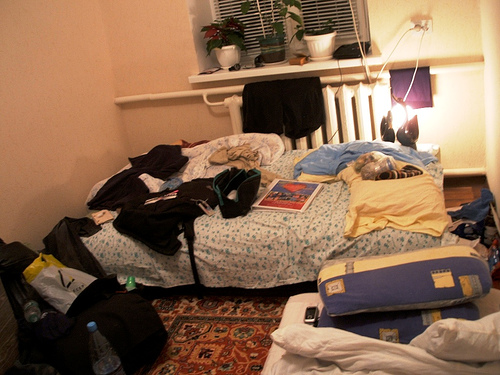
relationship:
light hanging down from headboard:
[386, 100, 414, 134] [216, 60, 448, 182]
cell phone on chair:
[303, 302, 319, 324] [261, 283, 496, 374]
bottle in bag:
[106, 276, 157, 301] [81, 251, 196, 349]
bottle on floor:
[85, 321, 123, 371] [172, 302, 261, 369]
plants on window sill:
[196, 0, 336, 58] [190, 45, 385, 82]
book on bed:
[250, 170, 330, 215] [67, 139, 457, 284]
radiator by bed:
[201, 78, 391, 153] [70, 148, 445, 294]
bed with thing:
[68, 139, 448, 300] [112, 172, 219, 256]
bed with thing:
[68, 139, 448, 300] [213, 137, 277, 194]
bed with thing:
[68, 139, 448, 300] [211, 163, 260, 217]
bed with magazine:
[68, 139, 448, 300] [250, 178, 325, 213]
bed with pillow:
[68, 139, 448, 300] [334, 160, 450, 238]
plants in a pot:
[196, 0, 336, 58] [217, 44, 245, 74]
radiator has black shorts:
[210, 76, 403, 154] [240, 76, 326, 140]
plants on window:
[196, 1, 343, 68] [192, 6, 373, 66]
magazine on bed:
[250, 178, 325, 213] [51, 128, 450, 291]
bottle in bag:
[125, 275, 136, 292] [98, 283, 170, 365]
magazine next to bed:
[250, 178, 325, 213] [91, 128, 468, 278]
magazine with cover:
[244, 165, 327, 242] [250, 162, 340, 237]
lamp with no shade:
[380, 102, 420, 149] [388, 74, 429, 145]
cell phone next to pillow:
[288, 278, 327, 335] [361, 182, 424, 220]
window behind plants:
[186, 4, 430, 74] [196, 0, 336, 58]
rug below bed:
[172, 294, 259, 371] [79, 125, 482, 293]